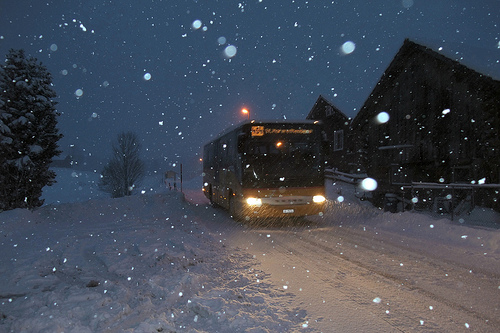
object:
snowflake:
[160, 115, 198, 153]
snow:
[145, 26, 420, 171]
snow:
[57, 257, 75, 264]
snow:
[128, 164, 170, 196]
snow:
[372, 102, 390, 124]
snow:
[278, 275, 293, 301]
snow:
[340, 38, 358, 56]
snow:
[360, 175, 379, 196]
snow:
[340, 126, 373, 144]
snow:
[221, 42, 236, 61]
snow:
[141, 73, 152, 83]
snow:
[270, 17, 322, 32]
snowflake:
[317, 147, 359, 174]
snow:
[3, 224, 84, 332]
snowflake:
[189, 59, 237, 89]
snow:
[6, 168, 498, 330]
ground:
[0, 164, 496, 330]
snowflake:
[450, 216, 489, 257]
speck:
[381, 243, 417, 295]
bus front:
[228, 117, 330, 223]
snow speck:
[295, 49, 321, 64]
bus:
[200, 119, 329, 226]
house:
[307, 36, 499, 195]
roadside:
[70, 177, 280, 320]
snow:
[3, 200, 496, 324]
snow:
[298, 53, 340, 74]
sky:
[224, 15, 383, 91]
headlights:
[223, 165, 352, 227]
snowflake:
[321, 73, 352, 116]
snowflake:
[373, 125, 408, 149]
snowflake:
[325, 193, 352, 213]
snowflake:
[277, 8, 320, 32]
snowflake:
[372, 304, 415, 320]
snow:
[256, 227, 398, 282]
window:
[326, 121, 353, 163]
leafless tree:
[110, 133, 145, 201]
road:
[368, 227, 451, 328]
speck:
[426, 302, 433, 309]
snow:
[400, 176, 480, 206]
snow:
[354, 55, 410, 77]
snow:
[86, 96, 127, 140]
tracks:
[291, 213, 492, 327]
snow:
[393, 230, 497, 279]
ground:
[3, 9, 492, 174]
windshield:
[236, 130, 324, 190]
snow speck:
[300, 2, 346, 17]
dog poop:
[85, 270, 108, 296]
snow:
[334, 192, 382, 242]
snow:
[343, 237, 471, 320]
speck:
[381, 136, 420, 172]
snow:
[404, 97, 464, 139]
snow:
[133, 50, 444, 212]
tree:
[2, 45, 63, 212]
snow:
[7, 102, 44, 165]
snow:
[393, 128, 420, 157]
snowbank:
[34, 202, 257, 326]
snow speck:
[156, 298, 177, 323]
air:
[2, 7, 498, 183]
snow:
[272, 59, 278, 65]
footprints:
[158, 227, 292, 324]